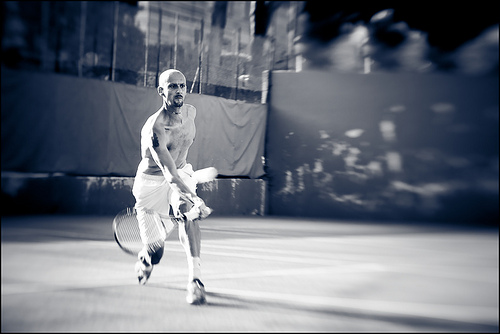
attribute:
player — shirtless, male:
[105, 62, 214, 306]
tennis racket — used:
[105, 202, 200, 262]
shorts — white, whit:
[126, 171, 208, 238]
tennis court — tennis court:
[0, 214, 498, 333]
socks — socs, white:
[179, 254, 205, 279]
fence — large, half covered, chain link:
[2, 1, 273, 102]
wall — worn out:
[258, 70, 493, 225]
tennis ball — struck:
[191, 167, 222, 180]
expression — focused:
[171, 74, 188, 107]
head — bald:
[153, 67, 191, 108]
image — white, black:
[3, 2, 497, 326]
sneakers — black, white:
[133, 258, 207, 313]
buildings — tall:
[133, 1, 318, 71]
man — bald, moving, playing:
[137, 68, 214, 306]